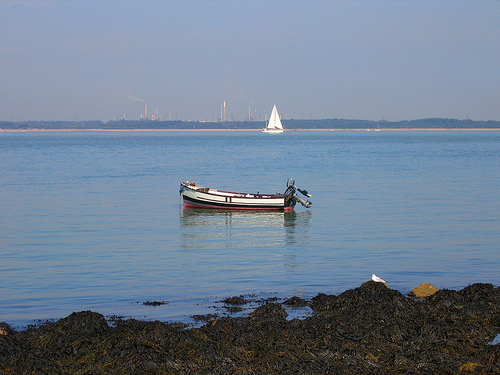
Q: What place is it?
A: It is a shore.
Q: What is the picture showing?
A: It is showing a shore.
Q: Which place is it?
A: It is a shore.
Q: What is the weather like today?
A: It is cloudless.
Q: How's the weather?
A: It is cloudless.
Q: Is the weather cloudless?
A: Yes, it is cloudless.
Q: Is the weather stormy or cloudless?
A: It is cloudless.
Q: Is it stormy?
A: No, it is cloudless.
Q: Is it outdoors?
A: Yes, it is outdoors.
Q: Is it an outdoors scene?
A: Yes, it is outdoors.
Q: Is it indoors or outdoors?
A: It is outdoors.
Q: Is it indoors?
A: No, it is outdoors.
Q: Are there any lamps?
A: No, there are no lamps.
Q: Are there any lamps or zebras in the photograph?
A: No, there are no lamps or zebras.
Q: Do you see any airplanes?
A: No, there are no airplanes.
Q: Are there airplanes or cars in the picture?
A: No, there are no airplanes or cars.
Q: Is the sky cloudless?
A: Yes, the sky is cloudless.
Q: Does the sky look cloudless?
A: Yes, the sky is cloudless.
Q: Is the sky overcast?
A: No, the sky is cloudless.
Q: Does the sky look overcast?
A: No, the sky is cloudless.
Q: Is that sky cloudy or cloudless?
A: The sky is cloudless.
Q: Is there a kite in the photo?
A: No, there are no kites.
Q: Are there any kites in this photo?
A: No, there are no kites.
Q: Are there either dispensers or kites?
A: No, there are no kites or dispensers.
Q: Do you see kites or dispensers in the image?
A: No, there are no kites or dispensers.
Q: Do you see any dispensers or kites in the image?
A: No, there are no kites or dispensers.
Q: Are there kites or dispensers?
A: No, there are no kites or dispensers.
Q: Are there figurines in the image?
A: No, there are no figurines.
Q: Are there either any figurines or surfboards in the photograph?
A: No, there are no figurines or surfboards.